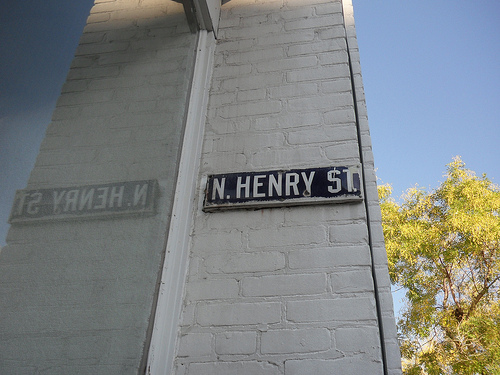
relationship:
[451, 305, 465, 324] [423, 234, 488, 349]
nest on tree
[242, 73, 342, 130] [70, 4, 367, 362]
brick on building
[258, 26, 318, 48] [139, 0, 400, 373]
brick on building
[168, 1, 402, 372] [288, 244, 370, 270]
column on brick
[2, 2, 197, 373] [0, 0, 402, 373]
window on building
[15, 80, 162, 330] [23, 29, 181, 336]
reflection on window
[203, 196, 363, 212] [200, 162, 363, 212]
paint on sign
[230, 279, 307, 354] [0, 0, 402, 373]
brick on building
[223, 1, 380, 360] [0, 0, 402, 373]
brick on building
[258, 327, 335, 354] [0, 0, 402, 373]
white brick on building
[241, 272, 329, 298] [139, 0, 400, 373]
brick on building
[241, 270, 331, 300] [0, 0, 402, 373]
brick on building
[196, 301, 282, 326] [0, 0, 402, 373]
brick on building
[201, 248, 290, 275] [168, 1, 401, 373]
brick on building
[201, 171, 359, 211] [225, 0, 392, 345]
sign on wall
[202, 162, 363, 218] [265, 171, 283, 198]
sign has letters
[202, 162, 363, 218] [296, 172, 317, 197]
sign has letters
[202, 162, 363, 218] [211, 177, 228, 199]
sign has letters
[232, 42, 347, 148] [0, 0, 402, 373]
wall on building